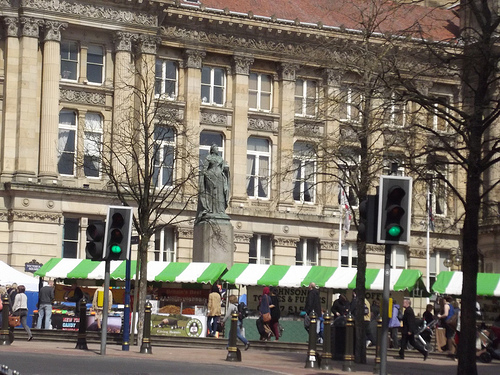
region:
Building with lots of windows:
[50, 37, 352, 205]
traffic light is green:
[372, 158, 422, 255]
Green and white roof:
[244, 250, 383, 302]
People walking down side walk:
[230, 288, 305, 355]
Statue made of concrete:
[187, 133, 249, 268]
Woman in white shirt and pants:
[3, 283, 49, 343]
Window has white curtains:
[62, 99, 122, 197]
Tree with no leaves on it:
[370, 15, 491, 148]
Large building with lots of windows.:
[18, 7, 498, 219]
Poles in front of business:
[228, 311, 235, 371]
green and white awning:
[29, 253, 498, 299]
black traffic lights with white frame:
[362, 168, 416, 251]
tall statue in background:
[193, 140, 238, 266]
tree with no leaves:
[343, 0, 498, 373]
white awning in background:
[0, 260, 51, 290]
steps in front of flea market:
[0, 325, 467, 362]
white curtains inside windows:
[56, 110, 457, 210]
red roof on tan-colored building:
[171, 0, 465, 45]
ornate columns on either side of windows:
[4, 15, 160, 198]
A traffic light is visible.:
[356, 162, 425, 248]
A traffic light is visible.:
[330, 131, 499, 261]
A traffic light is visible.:
[361, 138, 453, 253]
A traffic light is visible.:
[334, 80, 413, 285]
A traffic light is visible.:
[368, 153, 443, 313]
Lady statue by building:
[191, 138, 239, 224]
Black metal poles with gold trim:
[222, 303, 244, 363]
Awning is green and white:
[31, 254, 222, 290]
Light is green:
[387, 224, 404, 238]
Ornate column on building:
[39, 19, 69, 184]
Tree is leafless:
[82, 37, 227, 357]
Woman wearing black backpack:
[219, 285, 254, 356]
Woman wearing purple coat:
[385, 296, 402, 351]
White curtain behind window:
[82, 110, 103, 182]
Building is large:
[1, 0, 492, 374]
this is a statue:
[193, 140, 227, 217]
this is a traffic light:
[86, 205, 128, 337]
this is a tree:
[316, 41, 398, 248]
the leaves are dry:
[321, 118, 359, 192]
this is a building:
[24, 32, 95, 196]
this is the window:
[63, 40, 83, 84]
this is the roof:
[258, 1, 325, 18]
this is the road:
[44, 344, 91, 372]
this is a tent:
[234, 259, 299, 279]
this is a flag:
[422, 192, 441, 271]